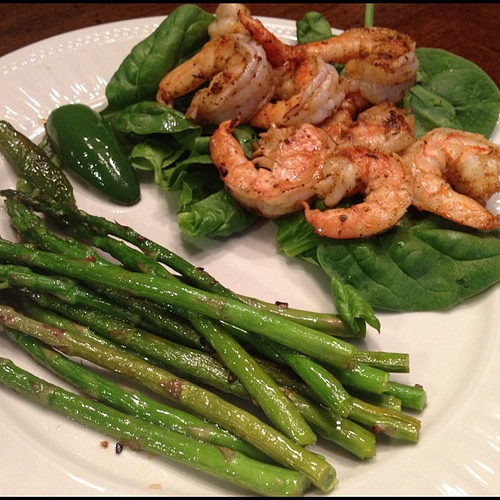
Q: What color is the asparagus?
A: Green.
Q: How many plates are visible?
A: One.